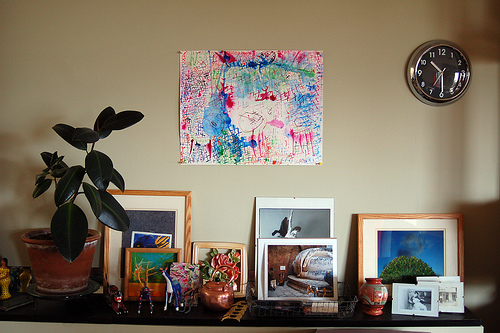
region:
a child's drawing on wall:
[175, 47, 322, 166]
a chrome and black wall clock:
[406, 39, 471, 105]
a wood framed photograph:
[355, 213, 465, 299]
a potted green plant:
[23, 107, 144, 288]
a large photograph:
[263, 240, 336, 300]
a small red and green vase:
[359, 273, 388, 315]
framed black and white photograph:
[390, 281, 439, 317]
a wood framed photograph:
[100, 185, 189, 294]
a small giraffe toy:
[131, 264, 153, 315]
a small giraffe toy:
[154, 263, 184, 313]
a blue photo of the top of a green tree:
[376, 228, 443, 285]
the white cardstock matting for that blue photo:
[363, 218, 458, 288]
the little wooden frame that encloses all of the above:
[357, 211, 463, 298]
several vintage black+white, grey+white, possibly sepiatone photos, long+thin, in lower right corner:
[388, 272, 466, 319]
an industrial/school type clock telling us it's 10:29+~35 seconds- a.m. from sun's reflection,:
[400, 35, 475, 110]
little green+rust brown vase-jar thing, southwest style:
[355, 270, 391, 320]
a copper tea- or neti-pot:
[191, 262, 236, 317]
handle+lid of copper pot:
[205, 262, 237, 284]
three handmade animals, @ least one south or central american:
[102, 262, 192, 322]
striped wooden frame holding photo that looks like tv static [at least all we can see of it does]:
[103, 189, 190, 298]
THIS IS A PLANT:
[15, 99, 156, 287]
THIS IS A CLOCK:
[399, 34, 480, 110]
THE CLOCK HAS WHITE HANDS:
[426, 57, 451, 97]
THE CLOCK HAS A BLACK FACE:
[403, 33, 472, 117]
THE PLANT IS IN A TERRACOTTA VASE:
[15, 216, 102, 298]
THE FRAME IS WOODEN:
[342, 200, 478, 320]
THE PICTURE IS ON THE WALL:
[168, 25, 335, 177]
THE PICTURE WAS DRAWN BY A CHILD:
[167, 40, 333, 182]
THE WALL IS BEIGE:
[0, 0, 495, 325]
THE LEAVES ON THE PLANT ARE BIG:
[27, 93, 143, 253]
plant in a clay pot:
[17, 104, 147, 303]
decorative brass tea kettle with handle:
[198, 263, 236, 311]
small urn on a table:
[356, 276, 389, 316]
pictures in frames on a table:
[99, 186, 469, 322]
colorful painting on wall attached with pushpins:
[176, 46, 328, 169]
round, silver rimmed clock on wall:
[402, 35, 474, 109]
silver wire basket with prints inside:
[245, 193, 359, 324]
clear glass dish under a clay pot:
[18, 223, 101, 299]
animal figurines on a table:
[103, 263, 185, 315]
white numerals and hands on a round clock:
[402, 37, 474, 107]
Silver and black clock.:
[405, 37, 472, 107]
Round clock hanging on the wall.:
[403, 36, 476, 107]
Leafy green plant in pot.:
[13, 106, 147, 305]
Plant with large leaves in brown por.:
[19, 102, 145, 302]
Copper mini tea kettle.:
[200, 255, 235, 308]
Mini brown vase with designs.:
[362, 275, 388, 316]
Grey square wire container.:
[242, 278, 359, 313]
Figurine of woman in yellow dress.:
[0, 249, 11, 301]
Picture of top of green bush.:
[356, 210, 461, 282]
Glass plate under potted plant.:
[20, 286, 105, 299]